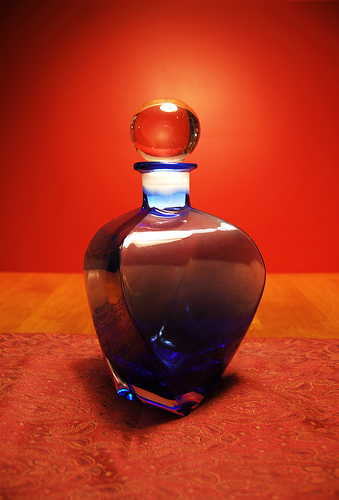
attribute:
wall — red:
[1, 1, 337, 272]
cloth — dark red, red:
[2, 328, 337, 494]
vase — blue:
[82, 162, 266, 415]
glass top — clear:
[126, 96, 201, 158]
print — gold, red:
[1, 330, 337, 498]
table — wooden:
[1, 270, 338, 336]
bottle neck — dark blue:
[132, 159, 197, 210]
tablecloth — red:
[1, 336, 337, 498]